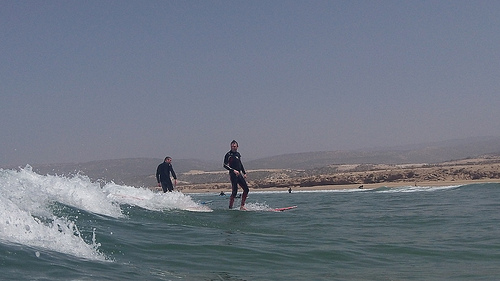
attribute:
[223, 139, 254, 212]
man — surfing, facing, wearing suit, verticle, standing, looking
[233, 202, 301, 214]
surfboard — red, pink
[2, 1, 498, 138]
sky — blue, clear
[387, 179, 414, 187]
beach — sandy, in background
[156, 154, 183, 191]
surfer — wearing, verticle, wet, male, surfing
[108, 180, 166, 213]
wave — breaking, white, big, small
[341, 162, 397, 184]
hill — in background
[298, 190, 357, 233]
water — blue, uncler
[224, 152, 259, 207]
suit — black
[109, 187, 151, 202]
water — white